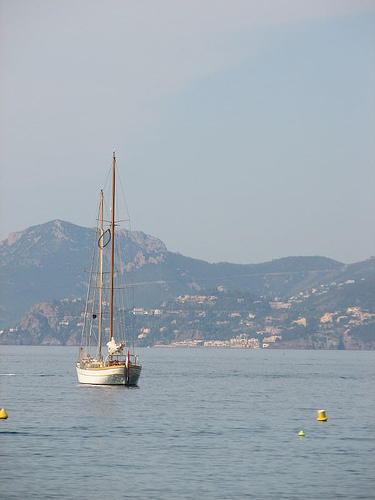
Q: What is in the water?
A: Sailboat.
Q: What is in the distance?
A: Mountains.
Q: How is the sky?
A: Hazy.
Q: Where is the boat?
A: In the ocean.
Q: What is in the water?
A: Buoys.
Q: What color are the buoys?
A: Yellow.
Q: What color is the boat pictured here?
A: White.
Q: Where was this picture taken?
A: The ocean.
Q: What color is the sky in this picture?
A: Grey.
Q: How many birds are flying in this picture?
A: Zero.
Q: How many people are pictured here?
A: Zero.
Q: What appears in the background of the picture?
A: A mountain.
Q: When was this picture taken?
A: Daytime.